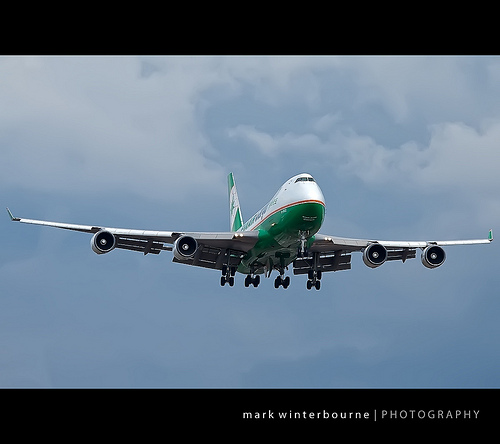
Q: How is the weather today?
A: It is cloudy.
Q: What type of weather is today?
A: It is cloudy.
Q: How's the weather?
A: It is cloudy.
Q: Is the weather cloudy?
A: Yes, it is cloudy.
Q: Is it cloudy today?
A: Yes, it is cloudy.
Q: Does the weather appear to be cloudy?
A: Yes, it is cloudy.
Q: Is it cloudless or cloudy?
A: It is cloudy.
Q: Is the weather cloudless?
A: No, it is cloudy.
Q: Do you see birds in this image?
A: No, there are no birds.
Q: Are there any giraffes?
A: No, there are no giraffes.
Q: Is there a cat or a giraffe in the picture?
A: No, there are no giraffes or cats.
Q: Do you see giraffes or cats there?
A: No, there are no giraffes or cats.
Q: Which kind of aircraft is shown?
A: The aircraft is a jet.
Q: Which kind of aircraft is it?
A: The aircraft is a jet.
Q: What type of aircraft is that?
A: This is a jet.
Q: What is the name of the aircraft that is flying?
A: The aircraft is a jet.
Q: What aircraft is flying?
A: The aircraft is a jet.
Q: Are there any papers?
A: No, there are no papers.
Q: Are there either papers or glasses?
A: No, there are no papers or glasses.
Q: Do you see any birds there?
A: No, there are no birds.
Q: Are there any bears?
A: No, there are no bears.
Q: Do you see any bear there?
A: No, there are no bears.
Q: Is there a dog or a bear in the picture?
A: No, there are no bears or dogs.